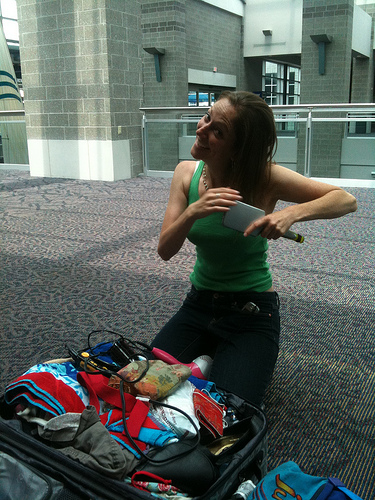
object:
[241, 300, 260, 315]
cell phone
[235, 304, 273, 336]
pocket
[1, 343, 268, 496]
suitcase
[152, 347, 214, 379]
hair dryer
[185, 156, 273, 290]
tank top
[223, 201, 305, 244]
brush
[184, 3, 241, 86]
wall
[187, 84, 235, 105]
doorway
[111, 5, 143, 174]
wall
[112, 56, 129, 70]
brick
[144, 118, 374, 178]
guard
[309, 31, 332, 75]
fixture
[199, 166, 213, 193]
necklace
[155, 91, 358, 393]
woman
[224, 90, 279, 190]
hair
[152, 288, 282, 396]
jeans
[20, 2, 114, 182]
column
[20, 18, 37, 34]
bricks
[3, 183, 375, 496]
floor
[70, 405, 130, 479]
clothes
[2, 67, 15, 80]
pattern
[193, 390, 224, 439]
wallet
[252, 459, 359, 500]
pack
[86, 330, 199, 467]
wire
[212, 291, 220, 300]
button